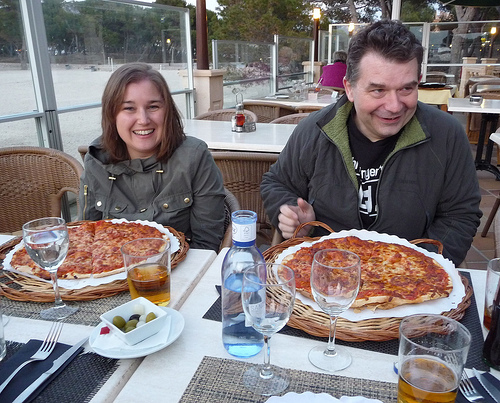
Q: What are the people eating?
A: Pizza.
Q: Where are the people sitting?
A: At the table.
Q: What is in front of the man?
A: A pizza.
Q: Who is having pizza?
A: The man and the girl.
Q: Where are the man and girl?
A: An outdoor cage.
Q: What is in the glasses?
A: Beer.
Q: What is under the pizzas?
A: White paper.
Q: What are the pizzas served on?
A: Large wicker plates.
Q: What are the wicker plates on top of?
A: Placemats.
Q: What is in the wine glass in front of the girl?
A: Water.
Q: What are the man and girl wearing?
A: Jackets.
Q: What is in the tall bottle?
A: Water.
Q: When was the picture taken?
A: During the day.